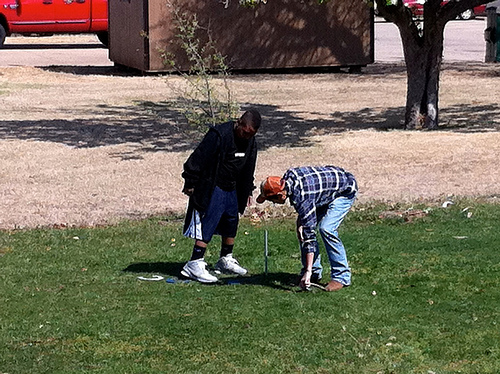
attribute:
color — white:
[177, 258, 219, 286]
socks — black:
[191, 241, 236, 260]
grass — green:
[1, 203, 498, 373]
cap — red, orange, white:
[257, 175, 285, 204]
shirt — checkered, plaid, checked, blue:
[281, 166, 360, 251]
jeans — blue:
[303, 194, 353, 292]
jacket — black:
[182, 120, 256, 203]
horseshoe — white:
[137, 271, 165, 282]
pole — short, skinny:
[259, 228, 273, 277]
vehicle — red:
[1, 1, 109, 52]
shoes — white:
[180, 253, 249, 285]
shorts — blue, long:
[181, 181, 241, 239]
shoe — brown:
[325, 275, 352, 292]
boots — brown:
[298, 267, 353, 292]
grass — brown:
[5, 68, 499, 217]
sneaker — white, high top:
[180, 257, 218, 286]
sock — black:
[190, 244, 208, 261]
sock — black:
[217, 244, 235, 259]